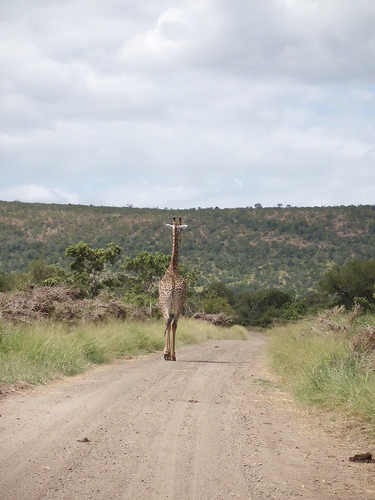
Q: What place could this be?
A: It is a road.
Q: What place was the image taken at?
A: It was taken at the road.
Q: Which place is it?
A: It is a road.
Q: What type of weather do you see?
A: It is cloudy.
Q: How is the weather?
A: It is cloudy.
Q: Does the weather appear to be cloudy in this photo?
A: Yes, it is cloudy.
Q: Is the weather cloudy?
A: Yes, it is cloudy.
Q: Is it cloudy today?
A: Yes, it is cloudy.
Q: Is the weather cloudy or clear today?
A: It is cloudy.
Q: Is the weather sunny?
A: No, it is cloudy.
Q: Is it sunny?
A: No, it is cloudy.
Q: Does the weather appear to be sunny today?
A: No, it is cloudy.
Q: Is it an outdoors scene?
A: Yes, it is outdoors.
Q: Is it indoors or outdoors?
A: It is outdoors.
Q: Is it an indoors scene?
A: No, it is outdoors.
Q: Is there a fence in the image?
A: No, there are no fences.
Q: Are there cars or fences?
A: No, there are no fences or cars.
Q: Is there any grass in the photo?
A: Yes, there is grass.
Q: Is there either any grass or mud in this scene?
A: Yes, there is grass.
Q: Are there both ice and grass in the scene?
A: No, there is grass but no ice.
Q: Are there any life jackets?
A: No, there are no life jackets.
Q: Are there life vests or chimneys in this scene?
A: No, there are no life vests or chimneys.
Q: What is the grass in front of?
A: The grass is in front of the trees.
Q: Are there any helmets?
A: No, there are no helmets.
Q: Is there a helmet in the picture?
A: No, there are no helmets.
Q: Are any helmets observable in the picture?
A: No, there are no helmets.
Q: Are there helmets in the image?
A: No, there are no helmets.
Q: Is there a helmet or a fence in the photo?
A: No, there are no helmets or fences.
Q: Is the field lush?
A: Yes, the field is lush.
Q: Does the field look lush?
A: Yes, the field is lush.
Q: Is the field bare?
A: No, the field is lush.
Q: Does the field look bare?
A: No, the field is lush.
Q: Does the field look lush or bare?
A: The field is lush.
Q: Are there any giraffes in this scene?
A: Yes, there is a giraffe.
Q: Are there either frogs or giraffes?
A: Yes, there is a giraffe.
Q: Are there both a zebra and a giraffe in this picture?
A: No, there is a giraffe but no zebras.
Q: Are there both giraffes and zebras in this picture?
A: No, there is a giraffe but no zebras.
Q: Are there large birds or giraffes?
A: Yes, there is a large giraffe.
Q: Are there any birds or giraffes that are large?
A: Yes, the giraffe is large.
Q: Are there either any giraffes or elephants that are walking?
A: Yes, the giraffe is walking.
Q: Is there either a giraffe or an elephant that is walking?
A: Yes, the giraffe is walking.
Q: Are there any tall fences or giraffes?
A: Yes, there is a tall giraffe.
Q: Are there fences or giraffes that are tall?
A: Yes, the giraffe is tall.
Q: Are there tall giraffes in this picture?
A: Yes, there is a tall giraffe.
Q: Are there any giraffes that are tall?
A: Yes, there is a giraffe that is tall.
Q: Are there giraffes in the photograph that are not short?
A: Yes, there is a tall giraffe.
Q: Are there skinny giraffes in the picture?
A: Yes, there is a skinny giraffe.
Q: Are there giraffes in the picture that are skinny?
A: Yes, there is a giraffe that is skinny.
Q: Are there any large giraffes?
A: Yes, there is a large giraffe.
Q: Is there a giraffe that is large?
A: Yes, there is a giraffe that is large.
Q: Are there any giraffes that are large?
A: Yes, there is a giraffe that is large.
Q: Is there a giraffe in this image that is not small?
A: Yes, there is a large giraffe.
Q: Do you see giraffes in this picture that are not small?
A: Yes, there is a large giraffe.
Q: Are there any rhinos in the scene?
A: No, there are no rhinos.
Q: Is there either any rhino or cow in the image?
A: No, there are no rhinos or cows.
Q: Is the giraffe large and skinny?
A: Yes, the giraffe is large and skinny.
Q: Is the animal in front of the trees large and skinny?
A: Yes, the giraffe is large and skinny.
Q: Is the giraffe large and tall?
A: Yes, the giraffe is large and tall.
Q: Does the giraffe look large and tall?
A: Yes, the giraffe is large and tall.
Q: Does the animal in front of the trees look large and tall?
A: Yes, the giraffe is large and tall.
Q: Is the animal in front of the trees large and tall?
A: Yes, the giraffe is large and tall.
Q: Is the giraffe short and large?
A: No, the giraffe is large but tall.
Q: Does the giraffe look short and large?
A: No, the giraffe is large but tall.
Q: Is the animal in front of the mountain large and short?
A: No, the giraffe is large but tall.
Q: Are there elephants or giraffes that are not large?
A: No, there is a giraffe but it is large.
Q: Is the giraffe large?
A: Yes, the giraffe is large.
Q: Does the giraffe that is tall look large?
A: Yes, the giraffe is large.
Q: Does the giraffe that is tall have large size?
A: Yes, the giraffe is large.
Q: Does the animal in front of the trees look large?
A: Yes, the giraffe is large.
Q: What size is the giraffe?
A: The giraffe is large.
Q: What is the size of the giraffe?
A: The giraffe is large.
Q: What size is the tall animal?
A: The giraffe is large.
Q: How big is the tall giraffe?
A: The giraffe is large.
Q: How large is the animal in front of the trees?
A: The giraffe is large.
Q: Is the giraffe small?
A: No, the giraffe is large.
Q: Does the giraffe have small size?
A: No, the giraffe is large.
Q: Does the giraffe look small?
A: No, the giraffe is large.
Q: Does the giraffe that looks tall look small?
A: No, the giraffe is large.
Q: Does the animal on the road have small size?
A: No, the giraffe is large.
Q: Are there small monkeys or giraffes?
A: No, there is a giraffe but it is large.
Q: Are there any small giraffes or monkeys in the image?
A: No, there is a giraffe but it is large.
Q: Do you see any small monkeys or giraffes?
A: No, there is a giraffe but it is large.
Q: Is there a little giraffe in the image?
A: No, there is a giraffe but it is large.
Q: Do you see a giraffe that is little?
A: No, there is a giraffe but it is large.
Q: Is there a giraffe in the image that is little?
A: No, there is a giraffe but it is large.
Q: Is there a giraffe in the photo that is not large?
A: No, there is a giraffe but it is large.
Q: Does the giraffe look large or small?
A: The giraffe is large.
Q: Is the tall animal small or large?
A: The giraffe is large.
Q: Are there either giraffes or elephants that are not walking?
A: No, there is a giraffe but it is walking.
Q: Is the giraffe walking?
A: Yes, the giraffe is walking.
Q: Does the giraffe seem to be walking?
A: Yes, the giraffe is walking.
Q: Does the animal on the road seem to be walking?
A: Yes, the giraffe is walking.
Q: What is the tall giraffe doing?
A: The giraffe is walking.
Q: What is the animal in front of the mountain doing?
A: The giraffe is walking.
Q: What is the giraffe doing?
A: The giraffe is walking.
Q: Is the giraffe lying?
A: No, the giraffe is walking.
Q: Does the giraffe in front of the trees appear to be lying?
A: No, the giraffe is walking.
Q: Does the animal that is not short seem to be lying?
A: No, the giraffe is walking.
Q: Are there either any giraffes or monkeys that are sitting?
A: No, there is a giraffe but it is walking.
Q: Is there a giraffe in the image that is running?
A: No, there is a giraffe but it is walking.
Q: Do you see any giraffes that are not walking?
A: No, there is a giraffe but it is walking.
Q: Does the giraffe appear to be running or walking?
A: The giraffe is walking.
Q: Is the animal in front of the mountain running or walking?
A: The giraffe is walking.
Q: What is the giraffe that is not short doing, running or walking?
A: The giraffe is walking.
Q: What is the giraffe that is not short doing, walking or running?
A: The giraffe is walking.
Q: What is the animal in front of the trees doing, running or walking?
A: The giraffe is walking.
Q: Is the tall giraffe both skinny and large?
A: Yes, the giraffe is skinny and large.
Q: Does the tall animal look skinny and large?
A: Yes, the giraffe is skinny and large.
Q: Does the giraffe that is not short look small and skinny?
A: No, the giraffe is skinny but large.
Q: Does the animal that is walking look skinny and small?
A: No, the giraffe is skinny but large.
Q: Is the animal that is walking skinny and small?
A: No, the giraffe is skinny but large.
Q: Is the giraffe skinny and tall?
A: Yes, the giraffe is skinny and tall.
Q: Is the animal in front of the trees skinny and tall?
A: Yes, the giraffe is skinny and tall.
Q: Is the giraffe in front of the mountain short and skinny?
A: No, the giraffe is skinny but tall.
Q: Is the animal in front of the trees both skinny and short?
A: No, the giraffe is skinny but tall.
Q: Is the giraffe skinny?
A: Yes, the giraffe is skinny.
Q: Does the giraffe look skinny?
A: Yes, the giraffe is skinny.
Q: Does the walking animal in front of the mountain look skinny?
A: Yes, the giraffe is skinny.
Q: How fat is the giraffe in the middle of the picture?
A: The giraffe is skinny.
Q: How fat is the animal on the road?
A: The giraffe is skinny.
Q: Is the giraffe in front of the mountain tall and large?
A: Yes, the giraffe is tall and large.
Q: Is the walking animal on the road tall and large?
A: Yes, the giraffe is tall and large.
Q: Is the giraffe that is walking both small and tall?
A: No, the giraffe is tall but large.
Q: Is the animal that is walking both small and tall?
A: No, the giraffe is tall but large.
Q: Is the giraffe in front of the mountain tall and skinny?
A: Yes, the giraffe is tall and skinny.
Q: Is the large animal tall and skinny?
A: Yes, the giraffe is tall and skinny.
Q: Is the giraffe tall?
A: Yes, the giraffe is tall.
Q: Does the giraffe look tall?
A: Yes, the giraffe is tall.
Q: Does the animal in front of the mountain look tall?
A: Yes, the giraffe is tall.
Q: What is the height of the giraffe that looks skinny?
A: The giraffe is tall.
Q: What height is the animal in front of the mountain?
A: The giraffe is tall.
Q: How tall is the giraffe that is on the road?
A: The giraffe is tall.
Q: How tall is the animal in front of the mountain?
A: The giraffe is tall.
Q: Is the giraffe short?
A: No, the giraffe is tall.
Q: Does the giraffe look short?
A: No, the giraffe is tall.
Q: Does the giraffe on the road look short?
A: No, the giraffe is tall.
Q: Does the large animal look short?
A: No, the giraffe is tall.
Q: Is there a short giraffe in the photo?
A: No, there is a giraffe but it is tall.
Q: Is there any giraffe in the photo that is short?
A: No, there is a giraffe but it is tall.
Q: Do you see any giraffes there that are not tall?
A: No, there is a giraffe but it is tall.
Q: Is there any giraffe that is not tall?
A: No, there is a giraffe but it is tall.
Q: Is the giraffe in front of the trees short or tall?
A: The giraffe is tall.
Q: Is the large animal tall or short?
A: The giraffe is tall.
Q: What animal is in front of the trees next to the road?
A: The animal is a giraffe.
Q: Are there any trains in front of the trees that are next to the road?
A: No, there is a giraffe in front of the trees.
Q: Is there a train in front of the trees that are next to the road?
A: No, there is a giraffe in front of the trees.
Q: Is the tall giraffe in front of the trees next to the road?
A: Yes, the giraffe is in front of the trees.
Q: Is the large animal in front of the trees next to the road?
A: Yes, the giraffe is in front of the trees.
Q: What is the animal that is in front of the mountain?
A: The animal is a giraffe.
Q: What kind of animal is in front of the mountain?
A: The animal is a giraffe.